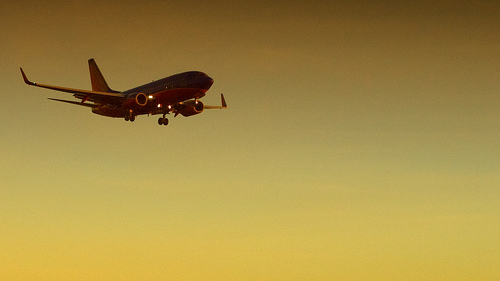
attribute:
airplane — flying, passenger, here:
[17, 41, 234, 135]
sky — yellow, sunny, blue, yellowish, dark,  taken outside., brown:
[10, 8, 499, 269]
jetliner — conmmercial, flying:
[17, 43, 235, 130]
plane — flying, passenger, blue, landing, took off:
[18, 38, 230, 144]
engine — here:
[122, 90, 147, 109]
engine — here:
[178, 98, 210, 117]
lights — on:
[141, 87, 200, 118]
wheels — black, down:
[120, 108, 170, 129]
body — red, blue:
[122, 67, 214, 107]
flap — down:
[44, 96, 114, 109]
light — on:
[33, 78, 38, 86]